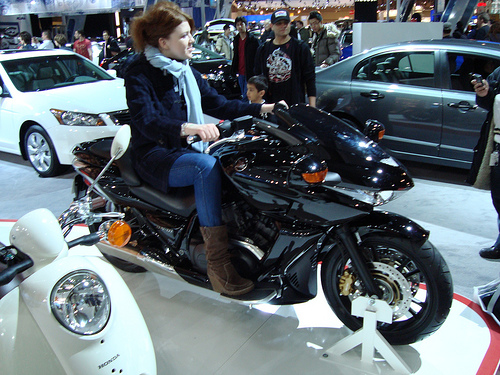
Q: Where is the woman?
A: Sitting on the motorcycle.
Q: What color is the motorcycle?
A: Black.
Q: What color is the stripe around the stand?
A: Red.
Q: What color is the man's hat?
A: Black.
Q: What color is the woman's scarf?
A: Blue.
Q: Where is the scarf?
A: Around the woman's neck.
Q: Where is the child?
A: In front of the man.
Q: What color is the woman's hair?
A: Brown.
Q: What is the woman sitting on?
A: A motorcycle.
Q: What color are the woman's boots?
A: Brown.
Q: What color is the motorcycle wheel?
A: Black.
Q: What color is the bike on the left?
A: White.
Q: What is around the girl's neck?
A: A scarf.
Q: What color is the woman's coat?
A: Blue.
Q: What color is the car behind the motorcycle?
A: White.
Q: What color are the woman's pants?
A: Blue.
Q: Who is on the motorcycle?
A: A woman.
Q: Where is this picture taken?
A: Auto show.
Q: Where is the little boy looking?
A: To the left.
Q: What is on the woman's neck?
A: Scarf.